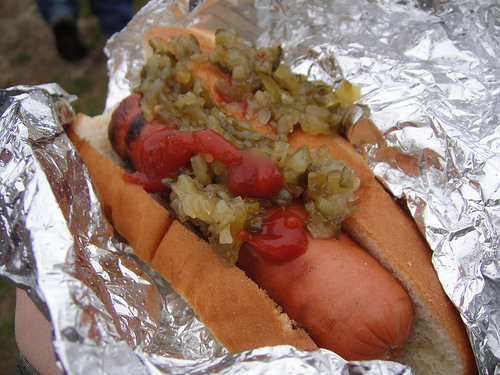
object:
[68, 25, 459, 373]
hotdog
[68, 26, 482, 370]
bun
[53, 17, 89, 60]
shoe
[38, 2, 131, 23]
pants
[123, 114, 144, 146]
burn mark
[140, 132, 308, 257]
ketchup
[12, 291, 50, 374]
hand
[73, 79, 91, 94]
grass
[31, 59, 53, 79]
dirt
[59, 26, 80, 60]
sole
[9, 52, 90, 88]
spots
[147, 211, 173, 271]
groove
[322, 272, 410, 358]
edge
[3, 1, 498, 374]
foil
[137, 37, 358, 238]
radish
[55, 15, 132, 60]
feet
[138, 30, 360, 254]
toppings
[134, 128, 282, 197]
ketchup squirt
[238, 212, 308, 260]
ketchup squirt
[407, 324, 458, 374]
bread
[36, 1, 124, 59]
person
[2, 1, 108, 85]
on ground